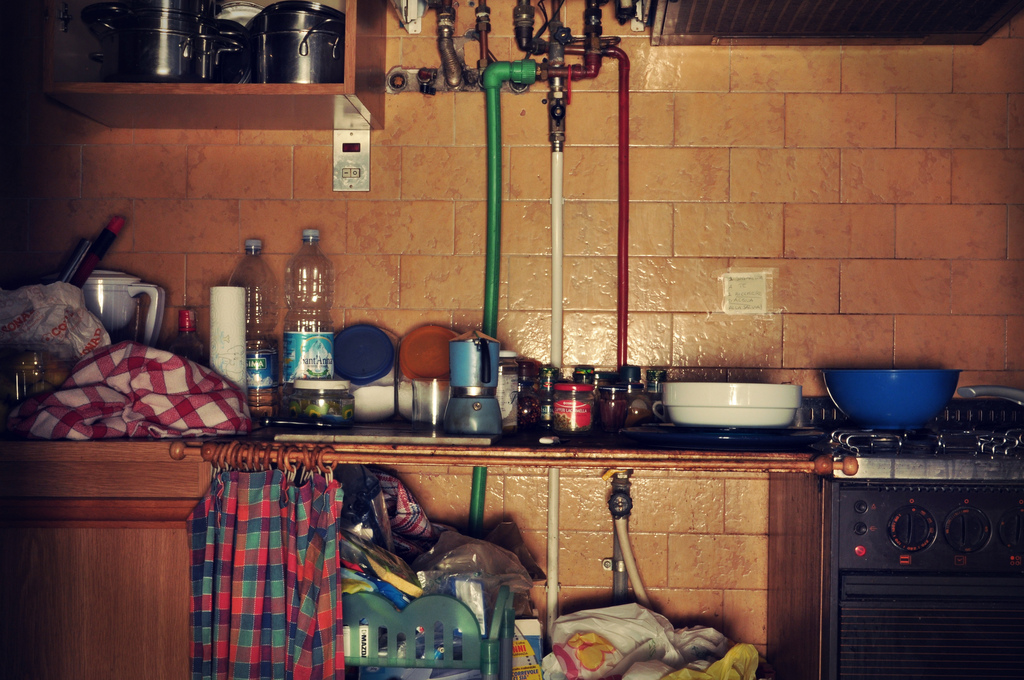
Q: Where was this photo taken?
A: In a kitchen.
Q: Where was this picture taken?
A: Inside a basement.